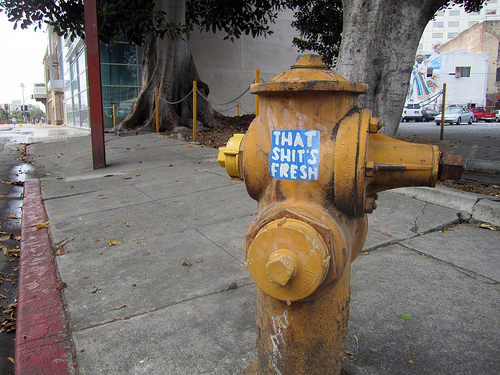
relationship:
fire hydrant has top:
[211, 41, 471, 374] [238, 49, 377, 102]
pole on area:
[80, 1, 116, 170] [0, 108, 498, 375]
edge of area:
[8, 135, 78, 374] [0, 108, 498, 375]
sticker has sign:
[267, 122, 326, 187] [270, 129, 321, 181]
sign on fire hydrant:
[267, 122, 326, 187] [211, 41, 471, 374]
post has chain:
[153, 83, 162, 135] [157, 89, 194, 105]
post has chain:
[191, 79, 199, 147] [157, 89, 194, 105]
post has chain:
[191, 79, 199, 147] [195, 88, 249, 105]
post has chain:
[253, 68, 265, 122] [195, 88, 249, 105]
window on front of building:
[61, 48, 95, 132] [30, 7, 334, 130]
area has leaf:
[0, 108, 498, 375] [120, 218, 136, 228]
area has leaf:
[0, 108, 498, 375] [104, 236, 126, 248]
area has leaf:
[0, 108, 498, 375] [37, 218, 57, 230]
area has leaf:
[0, 108, 498, 375] [183, 257, 193, 268]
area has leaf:
[0, 108, 498, 375] [93, 285, 100, 296]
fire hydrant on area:
[211, 41, 471, 374] [0, 108, 498, 375]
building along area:
[30, 7, 334, 130] [0, 108, 498, 375]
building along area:
[38, 21, 69, 127] [0, 108, 498, 375]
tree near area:
[0, 2, 275, 140] [0, 108, 498, 375]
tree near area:
[271, 2, 486, 161] [0, 108, 498, 375]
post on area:
[108, 99, 121, 127] [0, 108, 498, 375]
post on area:
[153, 83, 162, 135] [0, 108, 498, 375]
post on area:
[191, 79, 199, 147] [0, 108, 498, 375]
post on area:
[253, 68, 265, 122] [0, 108, 498, 375]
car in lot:
[434, 104, 476, 130] [376, 105, 499, 194]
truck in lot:
[466, 104, 496, 126] [376, 105, 499, 194]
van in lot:
[397, 102, 426, 123] [376, 105, 499, 194]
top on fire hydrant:
[238, 49, 377, 102] [211, 41, 471, 374]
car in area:
[434, 104, 476, 130] [400, 108, 498, 204]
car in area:
[466, 104, 496, 126] [400, 108, 498, 204]